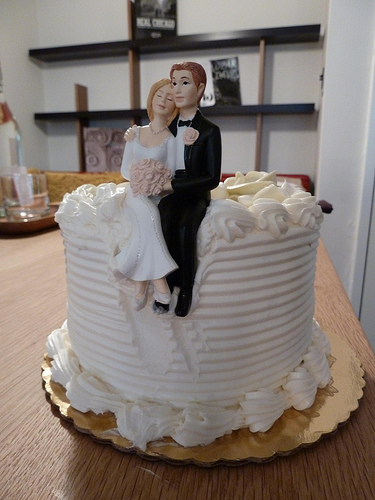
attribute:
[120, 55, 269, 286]
figure — male, couple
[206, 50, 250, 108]
book — black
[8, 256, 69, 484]
table — wood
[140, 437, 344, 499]
foil — gold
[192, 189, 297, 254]
artwork — floral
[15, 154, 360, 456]
cake — tiered, uncut, sitting, beautiful, simple, small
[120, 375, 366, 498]
shadows — cast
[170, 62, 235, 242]
man — sitting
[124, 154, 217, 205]
bouquet — pink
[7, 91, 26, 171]
bottle — glass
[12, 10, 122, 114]
walls — white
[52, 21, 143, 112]
case — brown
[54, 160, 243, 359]
frosting — flower, white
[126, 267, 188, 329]
shoes — white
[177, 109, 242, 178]
flower — small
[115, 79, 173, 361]
woman — sitting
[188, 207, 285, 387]
icing — smudged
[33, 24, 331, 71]
shelves — black